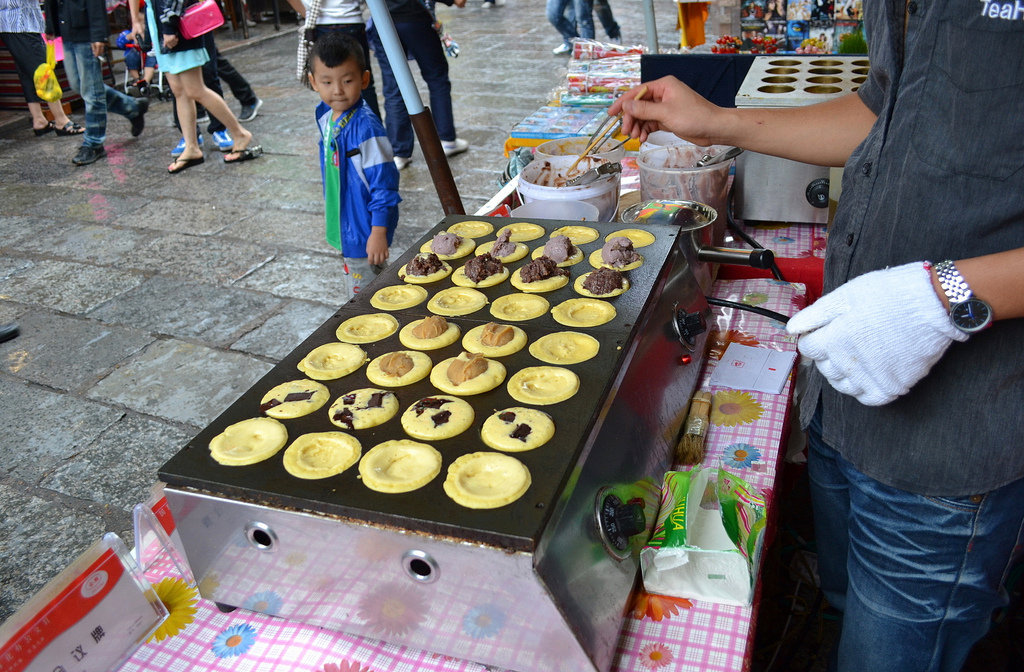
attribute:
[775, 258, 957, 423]
hand — man's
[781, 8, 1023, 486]
shirt — grey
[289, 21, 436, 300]
boy — young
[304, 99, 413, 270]
jacket — blue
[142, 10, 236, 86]
skirt — light blue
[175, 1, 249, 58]
purse — pink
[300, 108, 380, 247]
shirt — green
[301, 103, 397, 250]
jacket — blue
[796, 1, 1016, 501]
shirt — grey